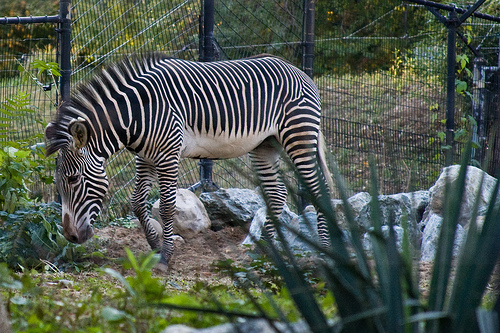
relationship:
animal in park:
[42, 53, 337, 273] [2, 1, 484, 329]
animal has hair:
[42, 53, 337, 273] [44, 50, 168, 157]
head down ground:
[35, 119, 117, 244] [7, 142, 498, 332]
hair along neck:
[62, 45, 169, 161] [77, 99, 106, 169]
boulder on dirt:
[140, 195, 234, 279] [169, 221, 246, 280]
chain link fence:
[14, 53, 64, 90] [311, 12, 441, 157]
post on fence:
[198, 0, 219, 186] [2, 5, 493, 205]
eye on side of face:
[64, 172, 80, 186] [53, 123, 108, 240]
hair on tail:
[286, 140, 341, 201] [291, 124, 356, 226]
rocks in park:
[148, 161, 498, 263] [77, 94, 431, 283]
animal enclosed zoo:
[48, 57, 337, 267] [2, 3, 497, 332]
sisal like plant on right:
[300, 60, 435, 245] [353, 172, 451, 320]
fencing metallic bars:
[321, 85, 441, 185] [2, 5, 498, 178]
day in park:
[276, 70, 426, 125] [354, 66, 475, 176]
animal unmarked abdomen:
[42, 53, 337, 273] [149, 115, 278, 157]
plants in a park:
[111, 246, 173, 311] [44, 22, 479, 321]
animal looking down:
[42, 53, 337, 273] [81, 230, 116, 300]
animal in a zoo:
[42, 53, 337, 273] [91, 196, 300, 333]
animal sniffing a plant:
[42, 53, 337, 273] [48, 222, 100, 333]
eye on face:
[67, 175, 80, 185] [53, 123, 108, 240]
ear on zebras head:
[45, 121, 54, 137] [44, 121, 112, 244]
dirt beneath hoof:
[71, 220, 280, 295] [150, 245, 175, 274]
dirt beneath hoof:
[71, 220, 280, 295] [147, 240, 162, 259]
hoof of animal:
[147, 240, 162, 259] [42, 53, 337, 273]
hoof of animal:
[150, 245, 175, 274] [42, 53, 337, 273]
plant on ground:
[8, 209, 53, 263] [1, 243, 116, 331]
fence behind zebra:
[315, 51, 490, 191] [69, 64, 407, 302]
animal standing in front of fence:
[42, 53, 337, 273] [1, 0, 498, 220]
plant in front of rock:
[148, 129, 495, 331] [151, 162, 498, 276]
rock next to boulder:
[203, 187, 255, 227] [150, 188, 211, 238]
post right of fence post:
[198, 0, 217, 62] [58, 3, 69, 210]